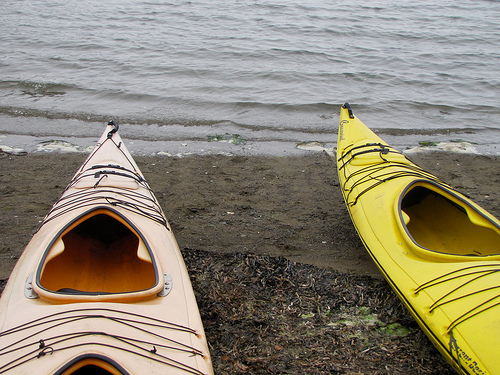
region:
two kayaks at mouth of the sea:
[1, 94, 498, 374]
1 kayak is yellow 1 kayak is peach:
[334, 96, 499, 374]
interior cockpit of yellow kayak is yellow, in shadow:
[391, 170, 497, 280]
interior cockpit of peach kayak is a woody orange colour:
[16, 191, 181, 326]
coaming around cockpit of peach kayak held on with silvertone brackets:
[20, 199, 177, 315]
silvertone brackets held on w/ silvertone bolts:
[20, 203, 177, 310]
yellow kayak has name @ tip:
[329, 116, 350, 147]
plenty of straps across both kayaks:
[0, 96, 498, 373]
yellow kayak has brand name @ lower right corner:
[441, 332, 492, 372]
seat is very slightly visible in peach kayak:
[51, 279, 142, 307]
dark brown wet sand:
[182, 156, 332, 256]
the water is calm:
[16, 6, 499, 144]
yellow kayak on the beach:
[289, 61, 498, 369]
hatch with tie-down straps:
[70, 157, 148, 199]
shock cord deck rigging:
[1, 299, 208, 368]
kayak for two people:
[16, 124, 198, 374]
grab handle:
[81, 104, 150, 156]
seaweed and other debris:
[198, 247, 402, 373]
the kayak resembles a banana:
[306, 75, 497, 374]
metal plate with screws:
[136, 261, 183, 303]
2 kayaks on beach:
[41, 109, 481, 370]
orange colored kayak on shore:
[13, 119, 195, 371]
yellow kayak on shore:
[298, 107, 498, 351]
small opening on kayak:
[4, 202, 180, 313]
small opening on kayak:
[378, 174, 497, 280]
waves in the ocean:
[263, 40, 320, 64]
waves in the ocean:
[13, 67, 103, 104]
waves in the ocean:
[169, 111, 231, 131]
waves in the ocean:
[118, 27, 188, 57]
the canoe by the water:
[293, 100, 498, 373]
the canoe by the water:
[1, 90, 217, 367]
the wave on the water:
[38, 60, 310, 147]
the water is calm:
[62, 12, 456, 92]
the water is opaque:
[176, 37, 362, 80]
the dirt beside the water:
[204, 177, 346, 342]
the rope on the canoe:
[9, 305, 219, 372]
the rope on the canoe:
[418, 263, 498, 370]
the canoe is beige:
[0, 111, 216, 373]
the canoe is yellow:
[316, 89, 498, 374]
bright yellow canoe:
[293, 65, 498, 366]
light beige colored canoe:
[7, 108, 186, 360]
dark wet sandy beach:
[9, 100, 487, 359]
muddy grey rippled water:
[8, 6, 490, 161]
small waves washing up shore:
[20, 58, 477, 199]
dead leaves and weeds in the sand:
[203, 247, 412, 367]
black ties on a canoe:
[25, 120, 193, 229]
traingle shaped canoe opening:
[20, 186, 225, 328]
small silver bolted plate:
[143, 258, 190, 309]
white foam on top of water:
[10, 128, 105, 181]